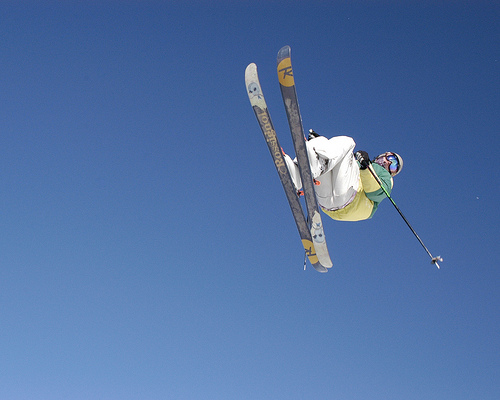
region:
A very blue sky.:
[0, 0, 499, 398]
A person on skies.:
[244, 45, 444, 275]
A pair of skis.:
[243, 45, 335, 275]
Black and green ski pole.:
[366, 161, 446, 268]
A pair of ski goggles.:
[383, 153, 400, 175]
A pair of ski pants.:
[306, 135, 361, 210]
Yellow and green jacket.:
[321, 162, 394, 222]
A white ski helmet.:
[392, 150, 405, 180]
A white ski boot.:
[305, 137, 323, 178]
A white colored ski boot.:
[281, 152, 305, 195]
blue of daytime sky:
[1, 2, 496, 393]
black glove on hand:
[355, 150, 372, 167]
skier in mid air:
[240, 41, 400, 271]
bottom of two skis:
[241, 42, 331, 272]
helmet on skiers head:
[385, 150, 400, 170]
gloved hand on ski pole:
[355, 147, 440, 267]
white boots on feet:
[281, 144, 323, 190]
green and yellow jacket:
[322, 161, 387, 216]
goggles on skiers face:
[384, 154, 396, 173]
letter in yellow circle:
[276, 58, 294, 88]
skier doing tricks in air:
[225, 29, 410, 281]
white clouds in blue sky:
[88, 164, 248, 321]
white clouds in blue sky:
[345, 317, 392, 372]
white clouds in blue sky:
[163, 235, 197, 271]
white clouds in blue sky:
[221, 263, 248, 302]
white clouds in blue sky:
[58, 229, 113, 302]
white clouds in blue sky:
[41, 64, 81, 134]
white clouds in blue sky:
[88, 261, 133, 323]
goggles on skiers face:
[387, 150, 401, 174]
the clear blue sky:
[8, 4, 225, 398]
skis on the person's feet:
[243, 44, 336, 277]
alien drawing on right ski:
[246, 78, 265, 105]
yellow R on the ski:
[298, 236, 319, 263]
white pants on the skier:
[308, 133, 360, 211]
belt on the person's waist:
[319, 203, 355, 212]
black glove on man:
[349, 150, 372, 166]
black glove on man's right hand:
[304, 126, 324, 140]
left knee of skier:
[336, 132, 357, 156]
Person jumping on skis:
[221, 35, 462, 297]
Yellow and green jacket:
[324, 162, 404, 227]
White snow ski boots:
[266, 140, 321, 192]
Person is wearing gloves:
[351, 148, 372, 173]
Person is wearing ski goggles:
[384, 148, 405, 176]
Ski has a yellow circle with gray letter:
[270, 40, 307, 113]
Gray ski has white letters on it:
[249, 106, 301, 224]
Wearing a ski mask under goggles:
[373, 148, 406, 180]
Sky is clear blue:
[16, 30, 233, 231]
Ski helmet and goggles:
[380, 145, 410, 179]